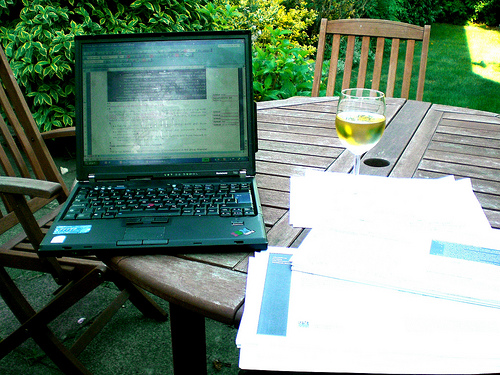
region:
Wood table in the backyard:
[102, 94, 499, 372]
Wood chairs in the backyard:
[0, 18, 431, 369]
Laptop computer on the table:
[39, 29, 269, 257]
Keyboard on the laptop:
[62, 180, 258, 219]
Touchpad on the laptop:
[114, 225, 169, 247]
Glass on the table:
[334, 86, 387, 174]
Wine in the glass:
[335, 110, 386, 155]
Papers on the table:
[235, 169, 498, 371]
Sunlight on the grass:
[464, 14, 499, 81]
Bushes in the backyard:
[0, 1, 498, 127]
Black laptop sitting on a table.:
[36, 13, 275, 255]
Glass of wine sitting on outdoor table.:
[309, 73, 398, 183]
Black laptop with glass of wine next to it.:
[33, 24, 424, 256]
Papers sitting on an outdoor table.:
[233, 169, 493, 372]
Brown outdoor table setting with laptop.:
[3, 11, 495, 361]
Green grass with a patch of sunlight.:
[433, 23, 498, 104]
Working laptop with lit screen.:
[33, 28, 277, 258]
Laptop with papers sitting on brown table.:
[38, 28, 499, 368]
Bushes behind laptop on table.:
[12, 3, 272, 265]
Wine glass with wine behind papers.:
[243, 78, 494, 358]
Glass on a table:
[331, 78, 390, 172]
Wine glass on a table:
[330, 81, 399, 172]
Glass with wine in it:
[332, 82, 390, 159]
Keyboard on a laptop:
[64, 177, 259, 222]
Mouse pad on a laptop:
[120, 219, 170, 245]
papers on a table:
[227, 174, 491, 374]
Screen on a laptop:
[77, 52, 251, 167]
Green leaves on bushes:
[0, 2, 312, 97]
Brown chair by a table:
[314, 13, 448, 110]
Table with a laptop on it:
[73, 71, 483, 353]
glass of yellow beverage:
[327, 78, 388, 173]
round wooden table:
[103, 88, 498, 368]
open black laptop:
[30, 20, 271, 270]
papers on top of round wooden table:
[230, 165, 498, 371]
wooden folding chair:
[1, 43, 166, 373]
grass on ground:
[436, 22, 498, 107]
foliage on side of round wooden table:
[3, 0, 323, 140]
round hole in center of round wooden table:
[361, 154, 393, 171]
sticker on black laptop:
[51, 223, 93, 238]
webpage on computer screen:
[78, 40, 250, 171]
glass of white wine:
[333, 81, 386, 176]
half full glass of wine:
[337, 84, 389, 174]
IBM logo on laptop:
[228, 224, 258, 240]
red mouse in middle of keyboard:
[146, 199, 153, 208]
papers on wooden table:
[241, 171, 498, 373]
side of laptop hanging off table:
[39, 172, 98, 262]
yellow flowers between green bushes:
[230, 0, 320, 66]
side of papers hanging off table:
[231, 322, 498, 374]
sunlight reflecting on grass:
[463, 2, 499, 82]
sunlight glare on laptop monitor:
[128, 40, 193, 167]